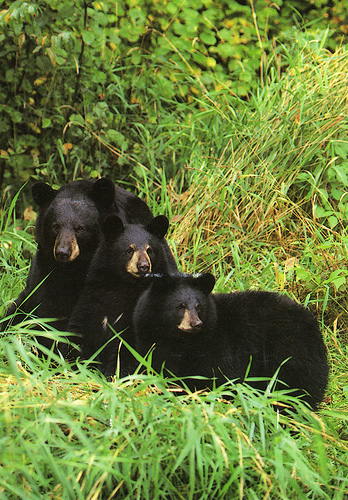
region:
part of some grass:
[213, 128, 280, 199]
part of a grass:
[141, 435, 181, 484]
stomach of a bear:
[273, 338, 320, 370]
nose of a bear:
[192, 317, 206, 328]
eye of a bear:
[171, 297, 185, 313]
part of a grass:
[130, 430, 168, 474]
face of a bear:
[172, 296, 210, 354]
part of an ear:
[149, 270, 177, 310]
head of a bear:
[179, 278, 197, 314]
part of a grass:
[47, 409, 107, 455]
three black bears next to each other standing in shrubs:
[1, 173, 329, 416]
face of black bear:
[98, 210, 170, 285]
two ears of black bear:
[30, 173, 117, 208]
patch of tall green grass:
[50, 390, 161, 498]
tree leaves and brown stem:
[71, 3, 92, 122]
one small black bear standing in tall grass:
[130, 272, 329, 414]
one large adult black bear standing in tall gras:
[3, 173, 177, 336]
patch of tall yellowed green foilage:
[171, 71, 299, 262]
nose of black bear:
[189, 316, 204, 329]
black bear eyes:
[49, 218, 87, 235]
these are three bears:
[44, 176, 195, 383]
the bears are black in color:
[31, 199, 189, 338]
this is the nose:
[183, 311, 200, 335]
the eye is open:
[124, 245, 137, 256]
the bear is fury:
[211, 306, 307, 372]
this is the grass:
[1, 405, 271, 495]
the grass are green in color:
[6, 403, 323, 491]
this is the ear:
[93, 178, 115, 203]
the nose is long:
[55, 238, 75, 264]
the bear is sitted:
[150, 280, 318, 392]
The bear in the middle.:
[102, 212, 179, 372]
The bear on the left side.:
[21, 180, 99, 316]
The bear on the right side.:
[135, 261, 328, 400]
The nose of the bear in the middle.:
[134, 262, 152, 274]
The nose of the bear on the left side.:
[47, 239, 75, 262]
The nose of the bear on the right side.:
[190, 319, 202, 331]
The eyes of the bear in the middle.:
[123, 244, 156, 259]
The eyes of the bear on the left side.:
[48, 219, 88, 233]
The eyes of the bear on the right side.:
[172, 295, 204, 314]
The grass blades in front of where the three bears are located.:
[2, 324, 346, 498]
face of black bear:
[33, 179, 104, 270]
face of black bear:
[136, 282, 222, 339]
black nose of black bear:
[49, 243, 78, 262]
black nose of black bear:
[131, 256, 146, 274]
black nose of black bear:
[179, 305, 212, 336]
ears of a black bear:
[23, 178, 122, 203]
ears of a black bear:
[91, 203, 172, 237]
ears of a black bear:
[126, 269, 217, 291]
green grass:
[35, 370, 203, 451]